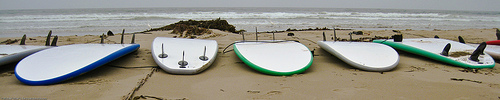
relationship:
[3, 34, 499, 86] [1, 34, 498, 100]
surfboards laying on ground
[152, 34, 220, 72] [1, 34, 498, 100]
board upside down on ground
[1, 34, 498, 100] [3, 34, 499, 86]
sand behind boards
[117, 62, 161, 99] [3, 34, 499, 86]
cable holding surfboards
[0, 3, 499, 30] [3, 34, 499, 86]
ocean behind surfboards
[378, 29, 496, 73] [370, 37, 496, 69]
surfboard has surfboard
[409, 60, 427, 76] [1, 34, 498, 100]
line drawn in sand